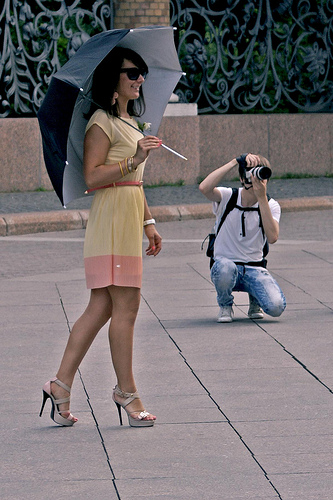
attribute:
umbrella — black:
[35, 25, 183, 210]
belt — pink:
[93, 182, 144, 190]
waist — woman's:
[92, 172, 143, 195]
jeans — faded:
[212, 255, 288, 322]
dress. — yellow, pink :
[83, 108, 150, 281]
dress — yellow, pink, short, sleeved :
[51, 61, 196, 335]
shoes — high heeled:
[39, 375, 156, 427]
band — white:
[143, 217, 155, 227]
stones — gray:
[166, 189, 195, 198]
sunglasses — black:
[118, 66, 148, 82]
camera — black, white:
[237, 149, 273, 188]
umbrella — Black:
[36, 13, 209, 209]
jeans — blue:
[210, 255, 286, 317]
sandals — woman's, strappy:
[38, 365, 157, 431]